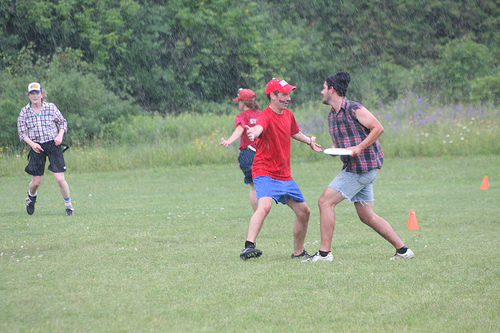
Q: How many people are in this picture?
A: Four.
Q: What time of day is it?
A: Daytime.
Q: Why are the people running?
A: They are playing frisbee.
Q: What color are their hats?
A: White and red.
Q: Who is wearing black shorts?
A: A man.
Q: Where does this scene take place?
A: On a grassy field.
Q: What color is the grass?
A: Green.